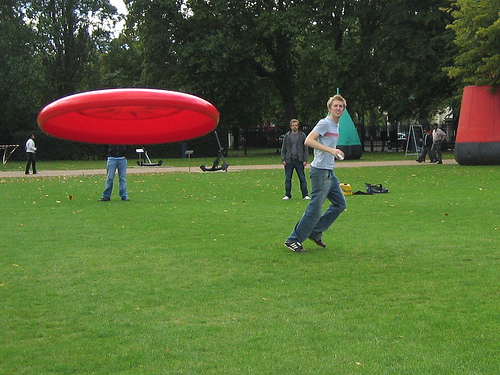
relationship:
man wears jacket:
[275, 115, 312, 202] [270, 126, 307, 165]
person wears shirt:
[23, 131, 40, 173] [23, 139, 38, 153]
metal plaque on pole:
[181, 146, 198, 158] [185, 149, 195, 176]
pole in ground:
[185, 149, 195, 176] [15, 170, 496, 360]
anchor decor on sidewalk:
[194, 144, 234, 172] [0, 155, 457, 182]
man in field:
[275, 115, 312, 202] [2, 138, 497, 373]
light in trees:
[89, 1, 132, 41] [61, 5, 345, 78]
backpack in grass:
[359, 177, 389, 197] [5, 156, 497, 372]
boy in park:
[285, 94, 349, 252] [1, 6, 497, 371]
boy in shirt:
[285, 94, 349, 252] [309, 115, 339, 171]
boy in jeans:
[285, 94, 349, 252] [287, 164, 344, 244]